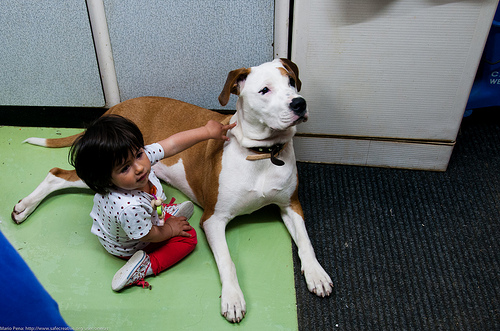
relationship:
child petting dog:
[70, 127, 202, 283] [61, 29, 376, 329]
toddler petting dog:
[44, 95, 257, 311] [14, 50, 391, 326]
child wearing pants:
[70, 127, 202, 283] [140, 210, 203, 267]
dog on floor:
[14, 50, 391, 326] [4, 118, 481, 329]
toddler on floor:
[44, 95, 257, 311] [4, 118, 481, 329]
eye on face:
[119, 157, 134, 178] [67, 86, 242, 301]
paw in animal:
[211, 282, 251, 324] [9, 49, 341, 330]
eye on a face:
[133, 150, 145, 160] [112, 145, 156, 186]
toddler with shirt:
[44, 95, 257, 311] [67, 146, 179, 253]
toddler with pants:
[44, 95, 257, 311] [137, 206, 212, 279]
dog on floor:
[14, 50, 391, 326] [297, 102, 498, 330]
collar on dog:
[225, 137, 325, 169] [68, 60, 395, 281]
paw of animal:
[295, 255, 342, 304] [23, 50, 345, 315]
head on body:
[70, 116, 150, 191] [68, 110, 182, 262]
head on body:
[70, 116, 150, 191] [69, 115, 231, 289]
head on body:
[219, 55, 309, 130] [12, 56, 332, 324]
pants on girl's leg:
[151, 199, 202, 270] [127, 217, 202, 287]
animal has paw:
[9, 49, 341, 330] [8, 191, 39, 229]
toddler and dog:
[44, 95, 257, 311] [165, 53, 335, 330]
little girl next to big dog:
[68, 115, 240, 292] [7, 57, 340, 329]